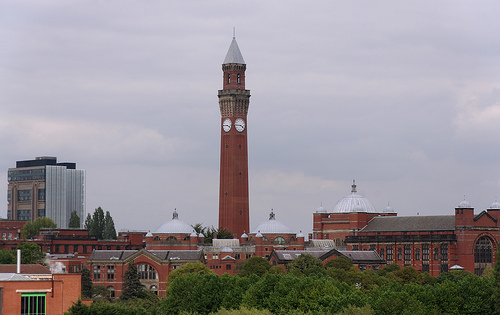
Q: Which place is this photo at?
A: It is at the town.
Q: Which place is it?
A: It is a town.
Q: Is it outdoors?
A: Yes, it is outdoors.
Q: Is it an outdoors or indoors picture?
A: It is outdoors.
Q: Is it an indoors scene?
A: No, it is outdoors.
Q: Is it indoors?
A: No, it is outdoors.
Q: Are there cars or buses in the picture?
A: No, there are no cars or buses.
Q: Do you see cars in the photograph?
A: No, there are no cars.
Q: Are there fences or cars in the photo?
A: No, there are no cars or fences.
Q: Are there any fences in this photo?
A: No, there are no fences.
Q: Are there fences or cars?
A: No, there are no fences or cars.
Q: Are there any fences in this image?
A: No, there are no fences.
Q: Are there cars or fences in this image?
A: No, there are no fences or cars.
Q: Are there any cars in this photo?
A: No, there are no cars.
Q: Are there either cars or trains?
A: No, there are no cars or trains.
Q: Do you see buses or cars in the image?
A: No, there are no cars or buses.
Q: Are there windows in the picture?
A: Yes, there is a window.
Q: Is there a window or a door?
A: Yes, there is a window.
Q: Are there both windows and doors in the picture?
A: No, there is a window but no doors.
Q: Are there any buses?
A: No, there are no buses.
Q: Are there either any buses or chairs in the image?
A: No, there are no buses or chairs.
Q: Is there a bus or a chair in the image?
A: No, there are no buses or chairs.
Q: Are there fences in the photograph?
A: No, there are no fences.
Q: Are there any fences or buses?
A: No, there are no fences or buses.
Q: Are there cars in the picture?
A: No, there are no cars.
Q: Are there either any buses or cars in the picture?
A: No, there are no cars or buses.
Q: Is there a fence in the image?
A: No, there are no fences.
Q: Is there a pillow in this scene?
A: No, there are no pillows.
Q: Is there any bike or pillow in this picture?
A: No, there are no pillows or bikes.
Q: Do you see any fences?
A: No, there are no fences.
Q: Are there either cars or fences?
A: No, there are no fences or cars.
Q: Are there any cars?
A: No, there are no cars.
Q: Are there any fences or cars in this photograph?
A: No, there are no cars or fences.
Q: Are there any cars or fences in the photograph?
A: No, there are no cars or fences.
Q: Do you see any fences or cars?
A: No, there are no cars or fences.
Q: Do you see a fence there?
A: No, there are no fences.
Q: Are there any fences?
A: No, there are no fences.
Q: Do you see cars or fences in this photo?
A: No, there are no fences or cars.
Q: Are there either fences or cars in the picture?
A: No, there are no cars or fences.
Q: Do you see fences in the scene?
A: No, there are no fences.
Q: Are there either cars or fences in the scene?
A: No, there are no fences or cars.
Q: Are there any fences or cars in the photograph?
A: No, there are no fences or cars.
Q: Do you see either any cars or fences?
A: No, there are no fences or cars.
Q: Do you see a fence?
A: No, there are no fences.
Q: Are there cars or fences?
A: No, there are no fences or cars.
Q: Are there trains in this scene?
A: No, there are no trains.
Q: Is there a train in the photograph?
A: No, there are no trains.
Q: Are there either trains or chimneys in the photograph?
A: No, there are no trains or chimneys.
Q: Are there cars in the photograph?
A: No, there are no cars.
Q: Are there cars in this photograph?
A: No, there are no cars.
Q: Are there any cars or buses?
A: No, there are no cars or buses.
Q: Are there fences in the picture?
A: No, there are no fences.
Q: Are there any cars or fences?
A: No, there are no fences or cars.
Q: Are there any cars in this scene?
A: No, there are no cars.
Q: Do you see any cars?
A: No, there are no cars.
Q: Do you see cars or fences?
A: No, there are no cars or fences.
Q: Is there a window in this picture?
A: Yes, there is a window.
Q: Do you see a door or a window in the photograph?
A: Yes, there is a window.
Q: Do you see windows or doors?
A: Yes, there is a window.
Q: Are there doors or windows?
A: Yes, there is a window.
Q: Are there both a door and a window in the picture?
A: No, there is a window but no doors.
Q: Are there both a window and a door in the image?
A: No, there is a window but no doors.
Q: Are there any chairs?
A: No, there are no chairs.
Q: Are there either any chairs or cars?
A: No, there are no chairs or cars.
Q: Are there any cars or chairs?
A: No, there are no chairs or cars.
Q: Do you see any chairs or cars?
A: No, there are no chairs or cars.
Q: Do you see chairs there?
A: No, there are no chairs.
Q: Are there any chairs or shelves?
A: No, there are no chairs or shelves.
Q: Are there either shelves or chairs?
A: No, there are no chairs or shelves.